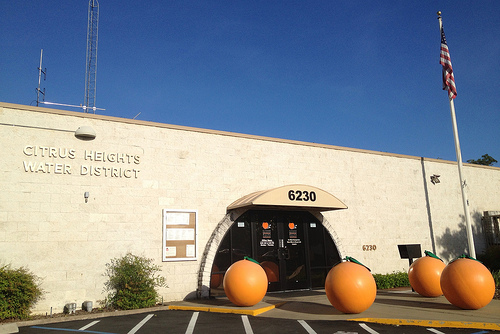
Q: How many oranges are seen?
A: Four.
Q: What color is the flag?
A: Red white and blue.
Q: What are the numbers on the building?
A: 6230.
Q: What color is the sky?
A: Blue.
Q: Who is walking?
A: No one.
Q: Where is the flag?
A: On the flag pole.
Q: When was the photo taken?
A: Daytime.